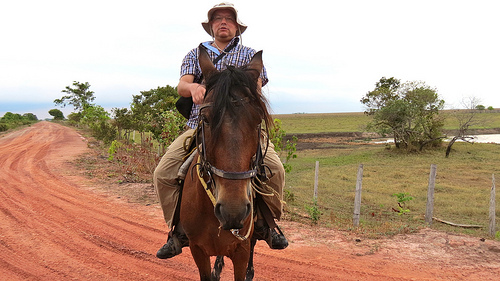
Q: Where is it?
A: This is at the path.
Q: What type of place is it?
A: It is a path.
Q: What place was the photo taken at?
A: It was taken at the path.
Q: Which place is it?
A: It is a path.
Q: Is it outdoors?
A: Yes, it is outdoors.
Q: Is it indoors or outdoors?
A: It is outdoors.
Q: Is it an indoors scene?
A: No, it is outdoors.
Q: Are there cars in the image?
A: No, there are no cars.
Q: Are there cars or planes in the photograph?
A: No, there are no cars or planes.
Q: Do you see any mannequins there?
A: No, there are no mannequins.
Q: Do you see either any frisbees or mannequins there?
A: No, there are no mannequins or frisbees.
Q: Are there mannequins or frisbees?
A: No, there are no mannequins or frisbees.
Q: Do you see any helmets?
A: No, there are no helmets.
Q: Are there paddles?
A: No, there are no paddles.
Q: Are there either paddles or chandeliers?
A: No, there are no paddles or chandeliers.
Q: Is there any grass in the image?
A: Yes, there is grass.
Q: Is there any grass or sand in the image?
A: Yes, there is grass.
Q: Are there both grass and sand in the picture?
A: No, there is grass but no sand.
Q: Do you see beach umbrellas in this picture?
A: No, there are no beach umbrellas.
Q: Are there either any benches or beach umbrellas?
A: No, there are no beach umbrellas or benches.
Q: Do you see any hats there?
A: Yes, there is a hat.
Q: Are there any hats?
A: Yes, there is a hat.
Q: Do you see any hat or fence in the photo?
A: Yes, there is a hat.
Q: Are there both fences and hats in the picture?
A: Yes, there are both a hat and a fence.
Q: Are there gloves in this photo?
A: No, there are no gloves.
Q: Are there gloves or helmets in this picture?
A: No, there are no gloves or helmets.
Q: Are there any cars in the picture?
A: No, there are no cars.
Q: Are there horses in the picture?
A: Yes, there is a horse.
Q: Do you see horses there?
A: Yes, there is a horse.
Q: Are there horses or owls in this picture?
A: Yes, there is a horse.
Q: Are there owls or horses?
A: Yes, there is a horse.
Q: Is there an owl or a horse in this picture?
A: Yes, there is a horse.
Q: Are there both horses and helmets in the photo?
A: No, there is a horse but no helmets.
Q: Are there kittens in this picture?
A: No, there are no kittens.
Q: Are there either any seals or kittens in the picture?
A: No, there are no kittens or seals.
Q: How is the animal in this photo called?
A: The animal is a horse.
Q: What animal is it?
A: The animal is a horse.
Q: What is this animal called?
A: That is a horse.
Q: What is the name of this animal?
A: That is a horse.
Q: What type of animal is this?
A: That is a horse.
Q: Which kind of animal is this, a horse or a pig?
A: That is a horse.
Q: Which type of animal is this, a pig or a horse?
A: That is a horse.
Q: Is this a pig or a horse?
A: This is a horse.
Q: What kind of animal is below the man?
A: The animal is a horse.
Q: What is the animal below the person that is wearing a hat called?
A: The animal is a horse.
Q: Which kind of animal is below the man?
A: The animal is a horse.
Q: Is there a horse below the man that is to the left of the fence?
A: Yes, there is a horse below the man.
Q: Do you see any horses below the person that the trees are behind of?
A: Yes, there is a horse below the man.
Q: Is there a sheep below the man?
A: No, there is a horse below the man.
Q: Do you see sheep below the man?
A: No, there is a horse below the man.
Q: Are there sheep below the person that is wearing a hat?
A: No, there is a horse below the man.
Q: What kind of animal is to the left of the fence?
A: The animal is a horse.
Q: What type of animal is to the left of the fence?
A: The animal is a horse.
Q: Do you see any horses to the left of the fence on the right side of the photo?
A: Yes, there is a horse to the left of the fence.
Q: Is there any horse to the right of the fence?
A: No, the horse is to the left of the fence.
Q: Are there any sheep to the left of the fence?
A: No, there is a horse to the left of the fence.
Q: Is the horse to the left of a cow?
A: No, the horse is to the left of a fence.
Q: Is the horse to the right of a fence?
A: No, the horse is to the left of a fence.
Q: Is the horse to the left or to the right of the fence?
A: The horse is to the left of the fence.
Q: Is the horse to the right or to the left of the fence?
A: The horse is to the left of the fence.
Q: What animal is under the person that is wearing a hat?
A: The horse is under the man.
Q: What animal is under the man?
A: The horse is under the man.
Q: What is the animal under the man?
A: The animal is a horse.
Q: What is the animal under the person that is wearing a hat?
A: The animal is a horse.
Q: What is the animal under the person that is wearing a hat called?
A: The animal is a horse.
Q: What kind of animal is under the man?
A: The animal is a horse.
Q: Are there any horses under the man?
A: Yes, there is a horse under the man.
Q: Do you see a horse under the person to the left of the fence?
A: Yes, there is a horse under the man.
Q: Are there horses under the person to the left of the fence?
A: Yes, there is a horse under the man.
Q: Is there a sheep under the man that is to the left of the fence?
A: No, there is a horse under the man.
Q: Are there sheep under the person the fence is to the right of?
A: No, there is a horse under the man.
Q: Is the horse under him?
A: Yes, the horse is under the man.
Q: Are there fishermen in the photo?
A: No, there are no fishermen.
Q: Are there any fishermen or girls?
A: No, there are no fishermen or girls.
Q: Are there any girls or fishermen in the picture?
A: No, there are no fishermen or girls.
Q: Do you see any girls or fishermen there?
A: No, there are no fishermen or girls.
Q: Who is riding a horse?
A: The man is riding a horse.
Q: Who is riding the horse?
A: The man is riding a horse.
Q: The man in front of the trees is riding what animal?
A: The man is riding a horse.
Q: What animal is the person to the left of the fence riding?
A: The man is riding a horse.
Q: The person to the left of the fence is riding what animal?
A: The man is riding a horse.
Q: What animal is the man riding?
A: The man is riding a horse.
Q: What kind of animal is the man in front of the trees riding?
A: The man is riding a horse.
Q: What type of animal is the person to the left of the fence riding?
A: The man is riding a horse.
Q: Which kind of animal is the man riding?
A: The man is riding a horse.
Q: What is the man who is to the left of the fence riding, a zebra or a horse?
A: The man is riding a horse.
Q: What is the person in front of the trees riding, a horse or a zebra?
A: The man is riding a horse.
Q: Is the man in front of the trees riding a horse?
A: Yes, the man is riding a horse.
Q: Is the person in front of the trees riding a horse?
A: Yes, the man is riding a horse.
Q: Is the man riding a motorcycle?
A: No, the man is riding a horse.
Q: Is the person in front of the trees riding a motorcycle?
A: No, the man is riding a horse.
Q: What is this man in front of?
A: The man is in front of the trees.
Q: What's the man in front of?
A: The man is in front of the trees.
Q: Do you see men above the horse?
A: Yes, there is a man above the horse.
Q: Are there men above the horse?
A: Yes, there is a man above the horse.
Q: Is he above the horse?
A: Yes, the man is above the horse.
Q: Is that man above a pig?
A: No, the man is above the horse.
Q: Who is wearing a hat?
A: The man is wearing a hat.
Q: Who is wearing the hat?
A: The man is wearing a hat.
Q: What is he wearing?
A: The man is wearing a hat.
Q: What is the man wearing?
A: The man is wearing a hat.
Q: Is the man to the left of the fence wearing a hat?
A: Yes, the man is wearing a hat.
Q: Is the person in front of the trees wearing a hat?
A: Yes, the man is wearing a hat.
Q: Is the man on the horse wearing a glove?
A: No, the man is wearing a hat.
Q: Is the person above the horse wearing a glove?
A: No, the man is wearing a hat.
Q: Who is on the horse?
A: The man is on the horse.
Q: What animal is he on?
A: The man is on the horse.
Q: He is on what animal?
A: The man is on the horse.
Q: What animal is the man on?
A: The man is on the horse.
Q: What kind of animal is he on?
A: The man is on the horse.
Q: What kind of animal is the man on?
A: The man is on the horse.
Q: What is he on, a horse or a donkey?
A: The man is on a horse.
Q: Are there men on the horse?
A: Yes, there is a man on the horse.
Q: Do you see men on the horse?
A: Yes, there is a man on the horse.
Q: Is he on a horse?
A: Yes, the man is on a horse.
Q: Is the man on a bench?
A: No, the man is on a horse.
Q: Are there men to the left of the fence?
A: Yes, there is a man to the left of the fence.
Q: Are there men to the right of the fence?
A: No, the man is to the left of the fence.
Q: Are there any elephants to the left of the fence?
A: No, there is a man to the left of the fence.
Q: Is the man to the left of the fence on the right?
A: Yes, the man is to the left of the fence.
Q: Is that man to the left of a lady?
A: No, the man is to the left of the fence.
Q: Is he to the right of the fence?
A: No, the man is to the left of the fence.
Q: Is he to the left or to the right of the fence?
A: The man is to the left of the fence.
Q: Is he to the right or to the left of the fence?
A: The man is to the left of the fence.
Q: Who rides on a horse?
A: The man rides on a horse.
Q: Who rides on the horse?
A: The man rides on a horse.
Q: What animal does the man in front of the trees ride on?
A: The man rides on a horse.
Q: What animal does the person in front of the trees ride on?
A: The man rides on a horse.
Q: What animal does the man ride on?
A: The man rides on a horse.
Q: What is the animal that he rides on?
A: The animal is a horse.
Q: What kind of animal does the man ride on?
A: The man rides on a horse.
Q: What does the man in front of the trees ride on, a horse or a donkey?
A: The man rides on a horse.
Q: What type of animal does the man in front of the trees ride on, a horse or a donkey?
A: The man rides on a horse.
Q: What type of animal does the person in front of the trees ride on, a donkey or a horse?
A: The man rides on a horse.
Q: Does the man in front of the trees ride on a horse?
A: Yes, the man rides on a horse.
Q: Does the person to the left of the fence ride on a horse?
A: Yes, the man rides on a horse.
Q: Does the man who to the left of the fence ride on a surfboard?
A: No, the man rides on a horse.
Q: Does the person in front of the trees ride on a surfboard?
A: No, the man rides on a horse.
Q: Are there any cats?
A: No, there are no cats.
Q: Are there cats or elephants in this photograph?
A: No, there are no cats or elephants.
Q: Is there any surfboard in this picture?
A: No, there are no surfboards.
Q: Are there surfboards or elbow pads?
A: No, there are no surfboards or elbow pads.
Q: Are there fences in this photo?
A: Yes, there is a fence.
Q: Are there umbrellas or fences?
A: Yes, there is a fence.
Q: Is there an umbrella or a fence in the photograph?
A: Yes, there is a fence.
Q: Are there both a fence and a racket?
A: No, there is a fence but no rackets.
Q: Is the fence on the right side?
A: Yes, the fence is on the right of the image.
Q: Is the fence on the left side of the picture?
A: No, the fence is on the right of the image.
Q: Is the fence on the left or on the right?
A: The fence is on the right of the image.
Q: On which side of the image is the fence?
A: The fence is on the right of the image.